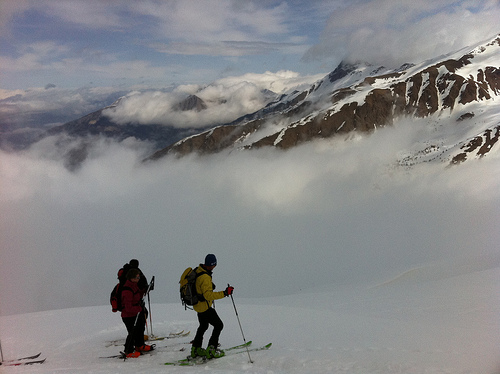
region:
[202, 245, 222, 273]
black and white snow hat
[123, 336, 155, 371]
red and black ski boots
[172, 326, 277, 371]
green and black skis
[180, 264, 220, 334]
yellow and black jacket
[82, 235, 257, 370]
three people skiing in snow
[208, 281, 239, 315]
one red and black glove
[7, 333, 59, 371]
two skis on the snow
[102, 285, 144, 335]
a maroon a nd black jacket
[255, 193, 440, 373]
white snow ansd white sky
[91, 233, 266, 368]
three people skiing together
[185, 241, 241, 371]
a man on skiis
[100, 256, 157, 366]
a man on skiis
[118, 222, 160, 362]
two people on skis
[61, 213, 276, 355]
three people on skis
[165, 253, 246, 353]
a man in a yellow jacket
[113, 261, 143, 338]
a person in a red jacket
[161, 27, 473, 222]
a snowy mountain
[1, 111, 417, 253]
fog around a mountain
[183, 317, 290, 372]
green skis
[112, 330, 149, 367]
red ski boots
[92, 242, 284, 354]
three people skiing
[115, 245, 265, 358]
the people on a mountain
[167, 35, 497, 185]
the mountain is very tall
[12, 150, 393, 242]
clouds beside the mountain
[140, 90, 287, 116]
the summit of the mountain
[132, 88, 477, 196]
the mountain is covered in snow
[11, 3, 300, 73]
clouds in the sky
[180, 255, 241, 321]
the man with the yellow jacket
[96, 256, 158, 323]
the man with the red jacket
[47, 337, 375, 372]
tracks in the snow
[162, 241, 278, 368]
person standing on skis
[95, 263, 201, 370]
person standing on skis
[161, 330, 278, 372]
pair of skis in the snow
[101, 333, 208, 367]
pair of skis in the snow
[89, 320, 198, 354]
pair of skis in the snow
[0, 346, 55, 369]
pair of skis in the snow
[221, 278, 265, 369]
long ski pole in the snow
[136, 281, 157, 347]
long ski pole being held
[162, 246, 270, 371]
person in a yellow coat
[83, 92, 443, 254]
fog is on the mountains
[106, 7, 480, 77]
clouds above the mountains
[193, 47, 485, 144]
snow on the mountains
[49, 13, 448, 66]
clouds in the sky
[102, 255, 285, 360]
the people are skiing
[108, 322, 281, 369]
people on the skiis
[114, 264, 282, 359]
people holding ski poles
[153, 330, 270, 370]
skiis in the snow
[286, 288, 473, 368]
snow is on the ground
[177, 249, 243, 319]
person has the backpack